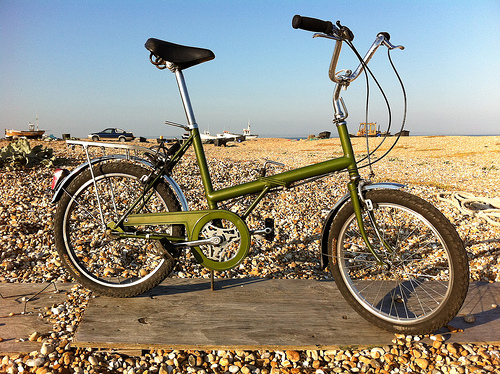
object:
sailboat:
[2, 112, 47, 142]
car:
[87, 127, 137, 142]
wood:
[68, 275, 499, 353]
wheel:
[50, 160, 187, 300]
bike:
[47, 14, 472, 338]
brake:
[375, 33, 404, 53]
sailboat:
[199, 125, 248, 146]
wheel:
[324, 189, 469, 339]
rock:
[11, 138, 485, 320]